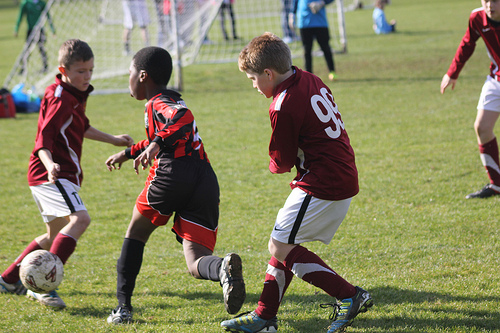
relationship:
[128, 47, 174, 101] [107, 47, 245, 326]
head of boy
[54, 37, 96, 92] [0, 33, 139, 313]
head of boy